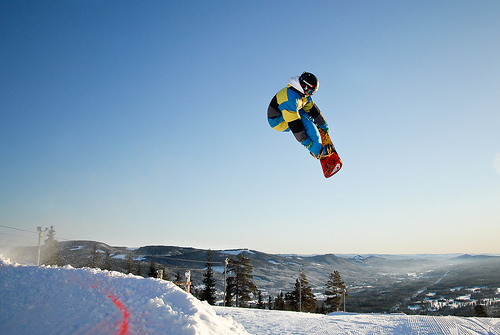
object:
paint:
[83, 279, 133, 332]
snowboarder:
[265, 70, 334, 157]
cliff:
[0, 260, 498, 333]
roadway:
[383, 277, 467, 319]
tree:
[220, 249, 253, 303]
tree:
[288, 270, 315, 312]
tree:
[324, 270, 347, 309]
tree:
[197, 248, 217, 303]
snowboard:
[311, 122, 344, 178]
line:
[85, 278, 137, 331]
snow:
[0, 252, 495, 334]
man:
[266, 71, 345, 179]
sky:
[3, 1, 498, 259]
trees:
[42, 243, 347, 314]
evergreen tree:
[282, 267, 318, 316]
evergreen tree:
[296, 274, 302, 307]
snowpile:
[0, 262, 238, 333]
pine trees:
[279, 268, 349, 311]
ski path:
[360, 286, 442, 334]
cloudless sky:
[0, 14, 499, 255]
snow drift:
[0, 254, 250, 334]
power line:
[7, 221, 56, 263]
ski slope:
[3, 256, 204, 328]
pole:
[222, 251, 230, 309]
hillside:
[307, 254, 495, 315]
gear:
[260, 82, 327, 139]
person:
[265, 66, 339, 169]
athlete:
[275, 66, 330, 125]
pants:
[285, 110, 333, 160]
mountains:
[2, 232, 497, 317]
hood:
[286, 73, 306, 94]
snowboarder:
[263, 71, 348, 179]